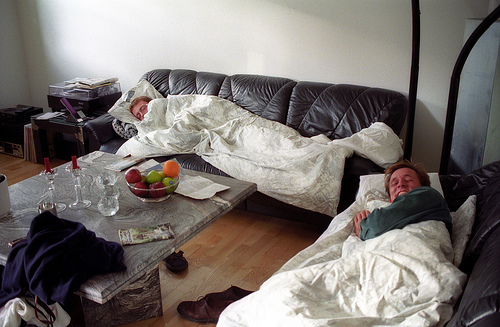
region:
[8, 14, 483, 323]
a living room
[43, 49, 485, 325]
two men lay on couches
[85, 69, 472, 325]
both men have white blankets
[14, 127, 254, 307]
a coffee table in a living room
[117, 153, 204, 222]
a bowl of fruit is on the table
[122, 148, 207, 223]
apples and oranges are in a glass bowl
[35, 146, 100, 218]
two candle sticks are on the table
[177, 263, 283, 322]
a pair of shoes is on the floor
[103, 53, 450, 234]
the couches are leather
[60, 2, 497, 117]
the walls are white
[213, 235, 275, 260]
brown wood flooring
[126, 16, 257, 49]
white wall in the background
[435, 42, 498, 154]
large black railings in the back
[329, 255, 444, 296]
wrinkles in the white sheet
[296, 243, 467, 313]
white sheet around man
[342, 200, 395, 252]
man's fingers on the sofa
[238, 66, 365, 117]
lines in black sofa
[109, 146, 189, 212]
bowl of fresh fruit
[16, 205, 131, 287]
blue clothing on table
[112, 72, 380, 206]
man sleeping on sofa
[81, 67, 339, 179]
A person on a couch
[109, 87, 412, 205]
A person sleeping on a couch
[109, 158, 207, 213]
A bowl of fruit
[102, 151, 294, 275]
A bowl of fruit on a table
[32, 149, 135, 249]
two candles on a table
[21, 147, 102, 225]
two red candles on a table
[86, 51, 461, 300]
Two people on couches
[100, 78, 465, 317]
Two people sleeping on couches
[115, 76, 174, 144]
A head on a pillow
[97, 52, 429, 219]
A black couch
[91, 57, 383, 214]
Man sleeping on a couch.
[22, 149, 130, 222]
Candles on a table.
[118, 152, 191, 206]
Fruit in a glass bowl.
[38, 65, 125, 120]
Record player on a small table.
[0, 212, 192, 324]
Clothes sitting on a table.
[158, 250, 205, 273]
One sandal on a floor.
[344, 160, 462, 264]
May wearing a green shirt.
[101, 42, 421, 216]
Leather couch with track arms.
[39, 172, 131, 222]
Glassware on a table.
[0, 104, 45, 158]
Stereo system next to records.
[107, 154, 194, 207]
bowl of fruit on table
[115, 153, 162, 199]
bowl of fruit on table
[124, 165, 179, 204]
bowl of fruit on table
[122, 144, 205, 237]
bowl of fruit on table